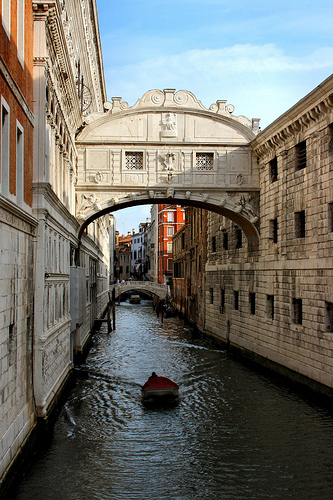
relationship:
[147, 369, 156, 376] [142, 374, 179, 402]
man driving boat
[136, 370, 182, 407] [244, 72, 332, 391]
boat going between building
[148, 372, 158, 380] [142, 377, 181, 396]
man driving boat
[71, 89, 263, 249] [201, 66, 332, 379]
archway connecting buildings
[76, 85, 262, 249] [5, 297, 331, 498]
bridge on river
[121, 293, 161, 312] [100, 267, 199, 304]
boat pass under bridge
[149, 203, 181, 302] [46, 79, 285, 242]
building behind bridge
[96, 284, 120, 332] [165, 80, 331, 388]
poles on side building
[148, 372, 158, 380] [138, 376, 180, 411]
man in boat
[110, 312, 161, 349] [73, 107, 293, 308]
water between building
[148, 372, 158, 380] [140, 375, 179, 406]
man on boat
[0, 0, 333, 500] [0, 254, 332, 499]
building on water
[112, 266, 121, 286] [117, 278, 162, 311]
person on bridge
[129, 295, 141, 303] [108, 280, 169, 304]
boat under bridge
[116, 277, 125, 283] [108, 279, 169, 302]
people are on bridge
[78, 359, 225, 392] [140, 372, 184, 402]
wake from boat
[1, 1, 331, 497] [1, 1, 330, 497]
river runs through city